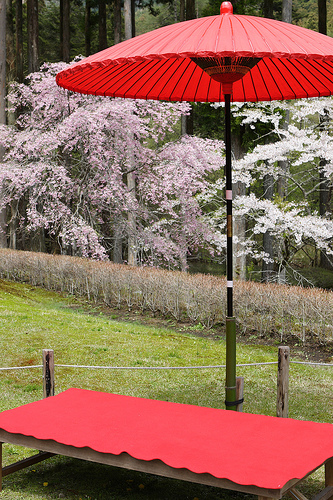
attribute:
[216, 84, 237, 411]
pole — made, umbrella, long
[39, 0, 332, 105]
umbrella — red, bright, large, open, roped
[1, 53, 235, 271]
tree — flowering, pink, covered, cherry, white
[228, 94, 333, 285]
tree — flowering, pink, covered, cherry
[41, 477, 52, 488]
flower — yellow, small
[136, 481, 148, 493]
flower — yellow, small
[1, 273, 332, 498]
lawn — grass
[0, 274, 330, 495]
grass — green, short, cut, low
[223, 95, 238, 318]
portion — black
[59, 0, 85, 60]
tree — tall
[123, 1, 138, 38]
tree — tall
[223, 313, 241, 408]
portion — green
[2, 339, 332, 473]
barrier — rope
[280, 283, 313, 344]
bush — bare, brown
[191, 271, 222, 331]
bush — bare, brown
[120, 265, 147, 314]
bush — bare, brown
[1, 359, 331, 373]
rope — white, thick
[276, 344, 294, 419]
post — short, wooden, weathered, brown, wood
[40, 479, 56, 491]
wildflower — yellow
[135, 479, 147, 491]
wildflower — yellow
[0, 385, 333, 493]
covering — red, bright, bench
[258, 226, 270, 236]
blossom — pink, pale, cherry, white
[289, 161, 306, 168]
blossom — pink, pale, cherry, white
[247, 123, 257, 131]
blossom — pink, pale, cherry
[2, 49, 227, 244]
flowers — white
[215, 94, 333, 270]
flowers — white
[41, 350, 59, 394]
post — weathered, wooden, brown, wood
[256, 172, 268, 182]
flower — cherry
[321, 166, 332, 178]
flower — cherry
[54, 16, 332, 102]
fabric — red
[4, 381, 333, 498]
stage — red, short, wooden, covered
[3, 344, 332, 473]
fence — made, wood, rope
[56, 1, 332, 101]
canopy — umbrella, red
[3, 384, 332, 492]
cot — red, displayed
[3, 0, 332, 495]
scene — asian, outdoor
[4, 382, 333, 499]
platform — covered, roped